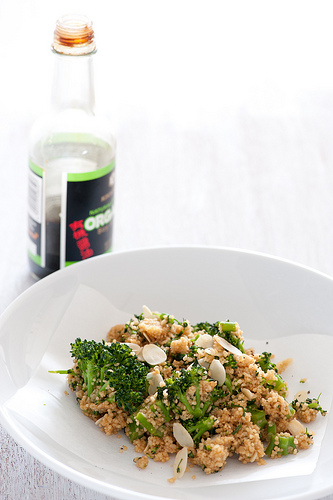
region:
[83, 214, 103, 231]
White letters OR on a bottle label.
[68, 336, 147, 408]
Biggest chunk of green broccoli in the bowl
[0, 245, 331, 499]
White bowl with broccoli, sliced almonds and quinoa inside.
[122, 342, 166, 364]
Three sliced almonds to the upper right of a large piece of broccoli.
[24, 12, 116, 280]
An open bottle of black liquid with a mostly black label.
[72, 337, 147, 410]
The largest green piece of broccoli.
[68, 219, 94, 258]
Red Asian symbols down a black label on an open bottle.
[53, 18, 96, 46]
The top rings of an open bottle that is stained brown.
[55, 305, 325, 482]
A gob of broccoli and sliced almonds in a bowl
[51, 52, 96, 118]
The clear neck of the open bottle.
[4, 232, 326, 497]
white bowl with prepared food in center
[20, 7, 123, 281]
clear glass bottle with black label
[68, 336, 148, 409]
green broccoli in the prepared meal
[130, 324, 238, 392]
slivered almonds on top of prepared meal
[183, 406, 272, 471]
quinoa or other grain in prepared meal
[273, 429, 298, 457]
piece of celery in prepared meal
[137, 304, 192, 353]
small pieces of chicken in a prepared meal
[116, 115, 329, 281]
white table under a white bowl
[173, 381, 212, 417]
green broccoli stems in prepared meal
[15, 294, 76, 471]
reflected light on white bowl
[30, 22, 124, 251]
SMALL GLASS BOTTLE OF SOY SAUCE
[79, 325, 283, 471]
GREEN BROCCOLI IN PLATE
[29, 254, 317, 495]
SMALL WHITE BOWL ON COUNTER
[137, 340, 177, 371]
SLICED ALMONDS IN BOWL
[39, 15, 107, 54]
OPEN TOP OF SAUCE BOTTLE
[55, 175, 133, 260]
BLACK AND GREEN LABEL ON BOTTLE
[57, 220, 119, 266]
RED ASIAN WRITING ON BOTTLE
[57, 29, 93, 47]
SAUCE AROUND OPENING OF BOTTLE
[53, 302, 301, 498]
SQUARE WHITE NAPKIN IN BOWL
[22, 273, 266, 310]
LIGHT REFLECTING OFF BOWL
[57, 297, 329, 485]
food on white plate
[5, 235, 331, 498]
white dish with food on it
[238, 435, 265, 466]
a clump of grains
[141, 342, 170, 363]
a slither resembling an almond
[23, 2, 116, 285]
bottle of condiment on table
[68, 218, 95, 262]
foreign lettering on bottle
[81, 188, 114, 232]
American lettering on bottle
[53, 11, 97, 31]
dispensing region of bottle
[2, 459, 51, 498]
table area where dish rests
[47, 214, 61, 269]
liquid condiment inside bottle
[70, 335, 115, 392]
a piece of green broccoli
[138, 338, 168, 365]
a slice of almond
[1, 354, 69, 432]
light shining on the plate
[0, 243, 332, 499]
a white porcelain bowl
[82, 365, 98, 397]
a green broccoli stem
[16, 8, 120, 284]
a bottle of soy sauce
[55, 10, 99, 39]
the mouth of the bottle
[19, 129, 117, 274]
the label on the bottle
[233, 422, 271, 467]
brown food on the plate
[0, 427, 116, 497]
a gray table top